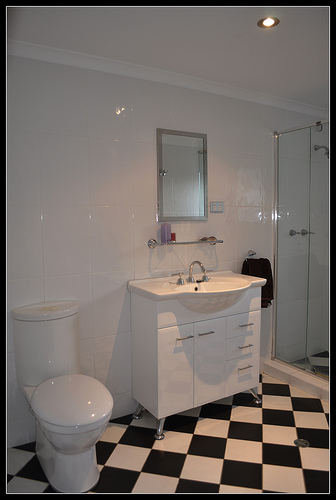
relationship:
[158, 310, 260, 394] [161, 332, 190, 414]
cabinet has door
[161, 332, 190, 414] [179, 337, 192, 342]
door has handle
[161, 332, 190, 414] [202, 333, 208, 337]
door has handle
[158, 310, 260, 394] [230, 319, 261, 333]
cabinet has drawer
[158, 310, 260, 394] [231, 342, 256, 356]
cabinet has drawer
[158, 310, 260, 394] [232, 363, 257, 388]
cabinet has drawer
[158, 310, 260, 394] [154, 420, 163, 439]
cabinet has leg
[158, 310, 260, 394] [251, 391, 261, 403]
cabinet has leg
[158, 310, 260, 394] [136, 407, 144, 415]
cabinet has leg